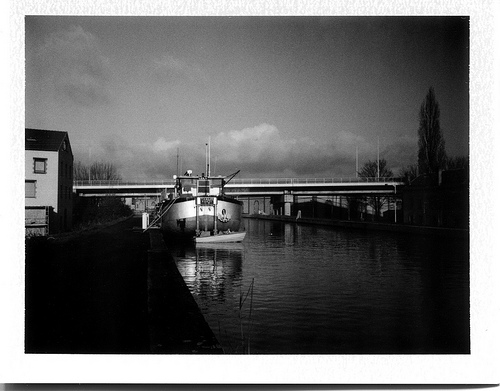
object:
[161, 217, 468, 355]
surface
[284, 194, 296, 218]
bridge foundation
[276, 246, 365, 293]
ripples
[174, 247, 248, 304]
reflection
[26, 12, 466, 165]
sky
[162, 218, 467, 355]
river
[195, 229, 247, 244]
boat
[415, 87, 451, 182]
tree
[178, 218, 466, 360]
canal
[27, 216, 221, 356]
side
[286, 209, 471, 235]
side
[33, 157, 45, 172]
window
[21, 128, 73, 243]
house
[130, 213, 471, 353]
water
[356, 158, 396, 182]
tree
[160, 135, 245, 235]
ship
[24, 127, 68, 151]
roof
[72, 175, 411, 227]
bridge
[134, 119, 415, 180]
clouds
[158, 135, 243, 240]
boat